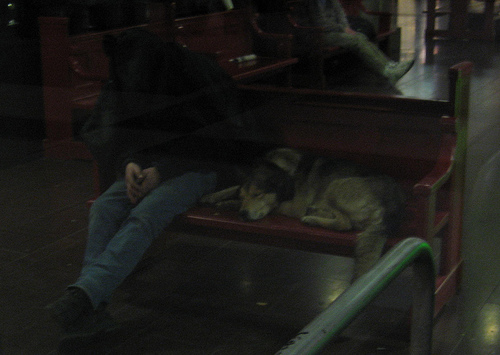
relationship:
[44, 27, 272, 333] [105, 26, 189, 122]
man has head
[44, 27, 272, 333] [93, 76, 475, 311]
man sitting on bench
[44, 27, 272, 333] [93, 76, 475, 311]
man sleeping on bench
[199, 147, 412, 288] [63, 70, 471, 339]
dog sleeping on bench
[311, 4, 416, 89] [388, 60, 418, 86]
person wearing shoes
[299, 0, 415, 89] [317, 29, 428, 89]
person wearing pants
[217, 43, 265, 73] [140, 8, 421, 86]
magazine is on the bench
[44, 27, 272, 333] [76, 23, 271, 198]
man wearing black jacket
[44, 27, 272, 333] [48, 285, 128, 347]
man wearing shoes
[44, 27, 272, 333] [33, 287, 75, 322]
man wearing black shoes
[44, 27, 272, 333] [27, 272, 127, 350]
man wearing shoes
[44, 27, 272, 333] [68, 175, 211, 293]
man wearing jeans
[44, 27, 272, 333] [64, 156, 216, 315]
man wearing jeans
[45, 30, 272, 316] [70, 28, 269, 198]
man wearing black jacket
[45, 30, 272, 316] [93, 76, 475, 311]
man sitting on bench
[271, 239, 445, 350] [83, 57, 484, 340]
railing on bench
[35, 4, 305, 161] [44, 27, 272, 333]
bench behind man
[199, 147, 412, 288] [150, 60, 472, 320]
dog on a seat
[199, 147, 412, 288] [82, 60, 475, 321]
dog on a seat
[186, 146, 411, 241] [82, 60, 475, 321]
dog on a seat